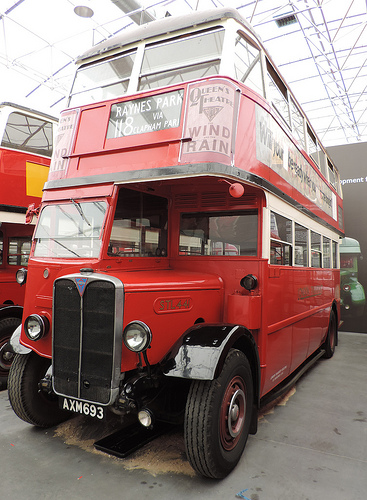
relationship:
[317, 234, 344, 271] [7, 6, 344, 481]
window on side of bus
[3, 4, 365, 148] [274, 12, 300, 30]
ceiling has vent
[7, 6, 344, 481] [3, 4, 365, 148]
bus has ceiling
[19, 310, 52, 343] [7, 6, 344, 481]
headlight on front of bus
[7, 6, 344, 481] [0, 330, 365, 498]
bus sitting on pavement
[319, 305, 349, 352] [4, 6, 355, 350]
tire on side of bus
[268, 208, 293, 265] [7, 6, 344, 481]
window on side of bus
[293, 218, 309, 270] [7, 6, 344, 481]
window on side of bus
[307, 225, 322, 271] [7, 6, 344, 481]
window on side of bus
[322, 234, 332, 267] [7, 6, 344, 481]
window on side of bus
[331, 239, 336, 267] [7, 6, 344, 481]
window on side of bus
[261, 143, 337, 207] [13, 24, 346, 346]
advertisement on side of bus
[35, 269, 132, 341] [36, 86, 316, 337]
vent on front of vehicle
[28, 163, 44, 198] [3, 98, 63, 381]
paint on side of bus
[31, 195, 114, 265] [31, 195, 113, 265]
reflection on window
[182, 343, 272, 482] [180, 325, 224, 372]
wheel with fender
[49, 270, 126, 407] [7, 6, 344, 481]
grill on bus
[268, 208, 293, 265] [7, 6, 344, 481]
window on bus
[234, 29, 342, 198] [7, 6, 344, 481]
windows on bus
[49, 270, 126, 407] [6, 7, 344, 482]
grill on red bus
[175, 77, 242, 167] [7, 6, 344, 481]
sign on bus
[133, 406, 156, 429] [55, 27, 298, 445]
light on bus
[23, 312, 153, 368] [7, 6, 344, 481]
headlights on bus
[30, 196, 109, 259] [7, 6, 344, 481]
window on bus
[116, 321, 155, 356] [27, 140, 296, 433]
headlight on red bus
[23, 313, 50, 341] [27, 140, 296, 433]
headlight on red bus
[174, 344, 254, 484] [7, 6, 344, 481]
tire on bus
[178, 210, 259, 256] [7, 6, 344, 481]
windshield on bus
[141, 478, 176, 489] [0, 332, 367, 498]
oil spot on pavement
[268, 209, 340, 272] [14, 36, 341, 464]
windows on bus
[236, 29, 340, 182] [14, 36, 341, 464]
windows on bus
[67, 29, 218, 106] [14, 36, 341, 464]
windows on bus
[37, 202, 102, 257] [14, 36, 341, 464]
windows on bus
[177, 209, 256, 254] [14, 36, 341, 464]
windows on bus